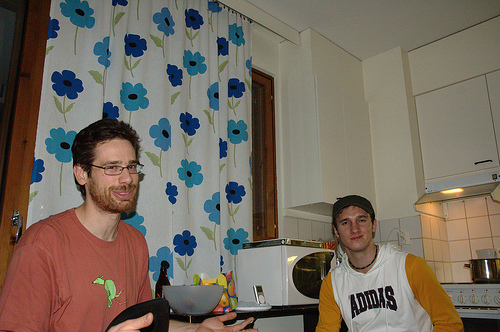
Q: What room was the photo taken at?
A: It was taken at the kitchen.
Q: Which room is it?
A: It is a kitchen.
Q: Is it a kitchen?
A: Yes, it is a kitchen.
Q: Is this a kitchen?
A: Yes, it is a kitchen.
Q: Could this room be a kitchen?
A: Yes, it is a kitchen.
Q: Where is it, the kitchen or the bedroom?
A: It is the kitchen.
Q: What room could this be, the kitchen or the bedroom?
A: It is the kitchen.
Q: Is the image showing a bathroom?
A: No, the picture is showing a kitchen.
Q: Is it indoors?
A: Yes, it is indoors.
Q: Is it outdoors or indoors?
A: It is indoors.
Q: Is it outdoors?
A: No, it is indoors.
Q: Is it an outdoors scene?
A: No, it is indoors.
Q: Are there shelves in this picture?
A: No, there are no shelves.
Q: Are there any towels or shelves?
A: No, there are no shelves or towels.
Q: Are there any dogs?
A: Yes, there is a dog.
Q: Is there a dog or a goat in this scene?
A: Yes, there is a dog.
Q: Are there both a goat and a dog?
A: No, there is a dog but no goats.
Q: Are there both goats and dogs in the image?
A: No, there is a dog but no goats.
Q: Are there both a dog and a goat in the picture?
A: No, there is a dog but no goats.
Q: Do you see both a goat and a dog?
A: No, there is a dog but no goats.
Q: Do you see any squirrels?
A: No, there are no squirrels.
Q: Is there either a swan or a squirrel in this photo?
A: No, there are no squirrels or swans.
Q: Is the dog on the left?
A: Yes, the dog is on the left of the image.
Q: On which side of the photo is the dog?
A: The dog is on the left of the image.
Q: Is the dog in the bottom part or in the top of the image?
A: The dog is in the bottom of the image.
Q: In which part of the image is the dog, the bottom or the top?
A: The dog is in the bottom of the image.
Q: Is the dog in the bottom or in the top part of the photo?
A: The dog is in the bottom of the image.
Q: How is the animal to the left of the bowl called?
A: The animal is a dog.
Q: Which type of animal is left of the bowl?
A: The animal is a dog.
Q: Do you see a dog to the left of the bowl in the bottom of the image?
A: Yes, there is a dog to the left of the bowl.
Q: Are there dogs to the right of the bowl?
A: No, the dog is to the left of the bowl.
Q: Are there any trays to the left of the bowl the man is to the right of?
A: No, there is a dog to the left of the bowl.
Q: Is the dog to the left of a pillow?
A: No, the dog is to the left of a bowl.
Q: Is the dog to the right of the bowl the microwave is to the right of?
A: No, the dog is to the left of the bowl.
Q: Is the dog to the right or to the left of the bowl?
A: The dog is to the left of the bowl.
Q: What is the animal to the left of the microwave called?
A: The animal is a dog.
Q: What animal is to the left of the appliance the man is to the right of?
A: The animal is a dog.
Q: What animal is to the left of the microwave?
A: The animal is a dog.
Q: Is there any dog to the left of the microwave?
A: Yes, there is a dog to the left of the microwave.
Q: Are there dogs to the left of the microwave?
A: Yes, there is a dog to the left of the microwave.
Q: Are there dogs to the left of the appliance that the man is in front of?
A: Yes, there is a dog to the left of the microwave.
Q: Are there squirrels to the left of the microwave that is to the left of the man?
A: No, there is a dog to the left of the microwave.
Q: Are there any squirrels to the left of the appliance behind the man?
A: No, there is a dog to the left of the microwave.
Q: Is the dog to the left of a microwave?
A: Yes, the dog is to the left of a microwave.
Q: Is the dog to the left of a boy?
A: No, the dog is to the left of a microwave.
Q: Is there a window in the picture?
A: Yes, there is a window.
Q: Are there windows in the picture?
A: Yes, there is a window.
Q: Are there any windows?
A: Yes, there is a window.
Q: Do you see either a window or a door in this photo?
A: Yes, there is a window.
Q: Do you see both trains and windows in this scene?
A: No, there is a window but no trains.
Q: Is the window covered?
A: Yes, the window is covered.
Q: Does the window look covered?
A: Yes, the window is covered.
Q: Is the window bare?
A: No, the window is covered.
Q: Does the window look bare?
A: No, the window is covered.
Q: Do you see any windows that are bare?
A: No, there is a window but it is covered.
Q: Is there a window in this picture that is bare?
A: No, there is a window but it is covered.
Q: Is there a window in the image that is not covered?
A: No, there is a window but it is covered.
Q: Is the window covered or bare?
A: The window is covered.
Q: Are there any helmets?
A: No, there are no helmets.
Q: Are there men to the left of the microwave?
A: Yes, there is a man to the left of the microwave.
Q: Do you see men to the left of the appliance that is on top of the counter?
A: Yes, there is a man to the left of the microwave.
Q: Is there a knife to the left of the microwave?
A: No, there is a man to the left of the microwave.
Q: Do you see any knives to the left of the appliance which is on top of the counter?
A: No, there is a man to the left of the microwave.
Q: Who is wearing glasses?
A: The man is wearing glasses.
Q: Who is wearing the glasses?
A: The man is wearing glasses.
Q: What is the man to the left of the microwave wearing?
A: The man is wearing glasses.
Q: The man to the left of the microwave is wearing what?
A: The man is wearing glasses.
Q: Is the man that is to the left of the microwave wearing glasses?
A: Yes, the man is wearing glasses.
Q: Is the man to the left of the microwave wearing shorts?
A: No, the man is wearing glasses.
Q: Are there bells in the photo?
A: No, there are no bells.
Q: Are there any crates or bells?
A: No, there are no bells or crates.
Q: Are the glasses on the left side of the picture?
A: Yes, the glasses are on the left of the image.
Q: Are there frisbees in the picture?
A: No, there are no frisbees.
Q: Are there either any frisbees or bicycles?
A: No, there are no frisbees or bicycles.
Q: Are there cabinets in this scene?
A: Yes, there is a cabinet.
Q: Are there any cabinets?
A: Yes, there is a cabinet.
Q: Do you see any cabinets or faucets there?
A: Yes, there is a cabinet.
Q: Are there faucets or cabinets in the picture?
A: Yes, there is a cabinet.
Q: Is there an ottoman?
A: No, there are no ottomen.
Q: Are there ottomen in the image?
A: No, there are no ottomen.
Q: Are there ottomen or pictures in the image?
A: No, there are no ottomen or pictures.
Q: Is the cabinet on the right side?
A: Yes, the cabinet is on the right of the image.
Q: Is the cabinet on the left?
A: No, the cabinet is on the right of the image.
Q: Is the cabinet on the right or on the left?
A: The cabinet is on the right of the image.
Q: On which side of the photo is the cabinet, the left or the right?
A: The cabinet is on the right of the image.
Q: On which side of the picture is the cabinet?
A: The cabinet is on the right of the image.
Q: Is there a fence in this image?
A: No, there are no fences.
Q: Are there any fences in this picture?
A: No, there are no fences.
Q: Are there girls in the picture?
A: No, there are no girls.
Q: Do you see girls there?
A: No, there are no girls.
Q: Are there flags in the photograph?
A: No, there are no flags.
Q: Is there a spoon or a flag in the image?
A: No, there are no flags or spoons.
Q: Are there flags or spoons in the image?
A: No, there are no flags or spoons.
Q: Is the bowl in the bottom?
A: Yes, the bowl is in the bottom of the image.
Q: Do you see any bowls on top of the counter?
A: Yes, there is a bowl on top of the counter.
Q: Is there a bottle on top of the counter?
A: No, there is a bowl on top of the counter.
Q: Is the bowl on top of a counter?
A: Yes, the bowl is on top of a counter.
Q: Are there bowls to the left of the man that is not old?
A: Yes, there is a bowl to the left of the man.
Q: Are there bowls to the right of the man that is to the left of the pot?
A: No, the bowl is to the left of the man.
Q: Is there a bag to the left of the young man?
A: No, there is a bowl to the left of the man.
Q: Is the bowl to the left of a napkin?
A: No, the bowl is to the left of the man.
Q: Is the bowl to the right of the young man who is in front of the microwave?
A: No, the bowl is to the left of the man.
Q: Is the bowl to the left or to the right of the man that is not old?
A: The bowl is to the left of the man.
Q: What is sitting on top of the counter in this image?
A: The bowl is sitting on top of the counter.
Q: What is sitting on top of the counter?
A: The bowl is sitting on top of the counter.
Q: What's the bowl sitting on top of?
A: The bowl is sitting on top of the counter.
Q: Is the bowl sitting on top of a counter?
A: Yes, the bowl is sitting on top of a counter.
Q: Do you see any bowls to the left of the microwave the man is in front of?
A: Yes, there is a bowl to the left of the microwave.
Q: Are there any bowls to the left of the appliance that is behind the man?
A: Yes, there is a bowl to the left of the microwave.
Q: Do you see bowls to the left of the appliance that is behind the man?
A: Yes, there is a bowl to the left of the microwave.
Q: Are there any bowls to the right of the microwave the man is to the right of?
A: No, the bowl is to the left of the microwave.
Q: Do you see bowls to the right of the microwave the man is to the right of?
A: No, the bowl is to the left of the microwave.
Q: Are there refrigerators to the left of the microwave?
A: No, there is a bowl to the left of the microwave.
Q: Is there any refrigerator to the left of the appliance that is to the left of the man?
A: No, there is a bowl to the left of the microwave.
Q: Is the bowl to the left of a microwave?
A: Yes, the bowl is to the left of a microwave.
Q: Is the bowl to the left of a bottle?
A: No, the bowl is to the left of a microwave.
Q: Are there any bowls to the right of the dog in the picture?
A: Yes, there is a bowl to the right of the dog.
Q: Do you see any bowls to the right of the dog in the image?
A: Yes, there is a bowl to the right of the dog.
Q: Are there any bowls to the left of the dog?
A: No, the bowl is to the right of the dog.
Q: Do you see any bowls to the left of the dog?
A: No, the bowl is to the right of the dog.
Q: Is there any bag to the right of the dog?
A: No, there is a bowl to the right of the dog.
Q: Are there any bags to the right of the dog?
A: No, there is a bowl to the right of the dog.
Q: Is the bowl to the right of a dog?
A: Yes, the bowl is to the right of a dog.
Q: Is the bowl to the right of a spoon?
A: No, the bowl is to the right of a dog.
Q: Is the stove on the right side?
A: Yes, the stove is on the right of the image.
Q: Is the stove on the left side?
A: No, the stove is on the right of the image.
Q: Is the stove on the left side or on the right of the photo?
A: The stove is on the right of the image.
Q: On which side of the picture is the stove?
A: The stove is on the right of the image.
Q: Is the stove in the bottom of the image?
A: Yes, the stove is in the bottom of the image.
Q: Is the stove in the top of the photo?
A: No, the stove is in the bottom of the image.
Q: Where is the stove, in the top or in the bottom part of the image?
A: The stove is in the bottom of the image.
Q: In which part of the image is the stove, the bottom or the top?
A: The stove is in the bottom of the image.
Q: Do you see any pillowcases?
A: No, there are no pillowcases.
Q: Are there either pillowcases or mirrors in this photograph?
A: No, there are no pillowcases or mirrors.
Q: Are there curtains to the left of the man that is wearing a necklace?
A: Yes, there is a curtain to the left of the man.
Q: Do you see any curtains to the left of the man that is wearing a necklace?
A: Yes, there is a curtain to the left of the man.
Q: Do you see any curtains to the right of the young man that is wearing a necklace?
A: No, the curtain is to the left of the man.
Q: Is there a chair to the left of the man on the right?
A: No, there is a curtain to the left of the man.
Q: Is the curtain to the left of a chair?
A: No, the curtain is to the left of the man.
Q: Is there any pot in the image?
A: Yes, there is a pot.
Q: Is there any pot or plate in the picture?
A: Yes, there is a pot.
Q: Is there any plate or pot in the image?
A: Yes, there is a pot.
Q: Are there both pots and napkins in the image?
A: No, there is a pot but no napkins.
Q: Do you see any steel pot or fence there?
A: Yes, there is a steel pot.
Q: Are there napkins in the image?
A: No, there are no napkins.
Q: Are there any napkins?
A: No, there are no napkins.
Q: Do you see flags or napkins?
A: No, there are no napkins or flags.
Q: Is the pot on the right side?
A: Yes, the pot is on the right of the image.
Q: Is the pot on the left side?
A: No, the pot is on the right of the image.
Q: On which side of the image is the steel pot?
A: The pot is on the right of the image.